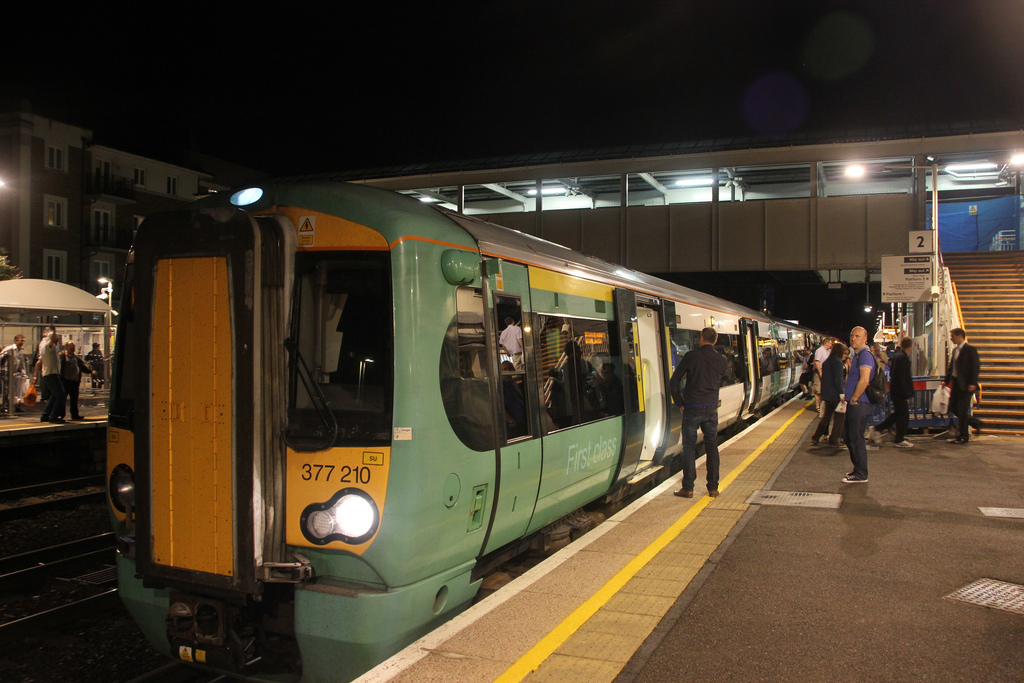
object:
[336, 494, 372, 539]
headlight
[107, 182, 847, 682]
train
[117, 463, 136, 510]
headlight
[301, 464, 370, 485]
numbers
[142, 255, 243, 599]
door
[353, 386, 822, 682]
line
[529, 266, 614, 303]
line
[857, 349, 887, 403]
backpack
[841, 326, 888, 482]
man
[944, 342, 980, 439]
suit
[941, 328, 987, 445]
man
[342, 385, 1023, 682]
platform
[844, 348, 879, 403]
shirt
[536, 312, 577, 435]
window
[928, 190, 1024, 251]
wall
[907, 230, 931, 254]
sign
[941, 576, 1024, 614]
square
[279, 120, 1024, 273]
walkway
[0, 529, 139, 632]
track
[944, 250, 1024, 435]
stairway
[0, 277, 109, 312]
canopy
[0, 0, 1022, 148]
sky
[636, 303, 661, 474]
doorway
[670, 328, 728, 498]
man